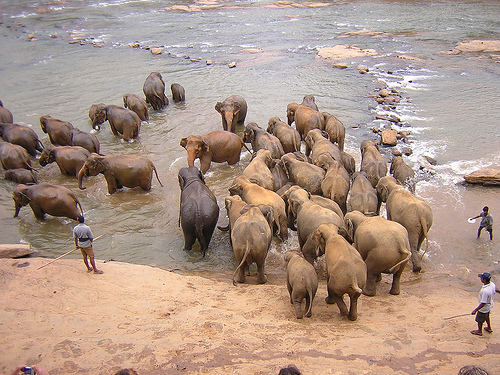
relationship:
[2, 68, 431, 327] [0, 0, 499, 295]
elephants going in river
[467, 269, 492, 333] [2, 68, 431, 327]
man looking at elephants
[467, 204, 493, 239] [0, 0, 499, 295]
kid in river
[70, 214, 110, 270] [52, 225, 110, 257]
man holding stick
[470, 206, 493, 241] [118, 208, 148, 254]
kid in river